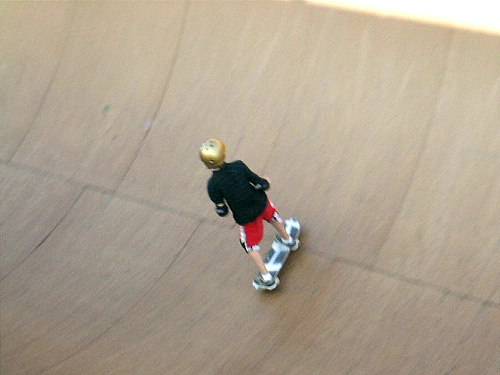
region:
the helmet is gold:
[198, 136, 225, 169]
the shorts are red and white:
[240, 196, 275, 244]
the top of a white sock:
[260, 270, 271, 282]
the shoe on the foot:
[250, 272, 277, 289]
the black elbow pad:
[213, 205, 228, 217]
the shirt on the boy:
[207, 160, 268, 225]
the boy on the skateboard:
[199, 137, 299, 289]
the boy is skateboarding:
[198, 136, 298, 288]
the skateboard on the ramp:
[253, 215, 299, 290]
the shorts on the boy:
[238, 197, 275, 247]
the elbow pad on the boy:
[214, 201, 229, 219]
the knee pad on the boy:
[237, 235, 260, 254]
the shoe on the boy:
[250, 272, 277, 290]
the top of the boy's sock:
[258, 271, 271, 282]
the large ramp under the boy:
[0, 0, 499, 372]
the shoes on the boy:
[253, 232, 300, 287]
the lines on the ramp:
[0, 0, 495, 373]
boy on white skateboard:
[196, 134, 307, 296]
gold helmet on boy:
[193, 133, 231, 168]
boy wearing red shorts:
[241, 195, 296, 250]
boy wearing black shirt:
[208, 157, 270, 225]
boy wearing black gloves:
[213, 175, 279, 215]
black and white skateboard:
[251, 214, 310, 296]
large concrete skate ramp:
[11, 0, 498, 353]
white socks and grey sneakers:
[254, 230, 299, 291]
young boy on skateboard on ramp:
[189, 132, 300, 304]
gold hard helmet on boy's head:
[199, 135, 226, 165]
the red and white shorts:
[238, 195, 278, 247]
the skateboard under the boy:
[254, 217, 300, 291]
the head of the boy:
[199, 135, 226, 170]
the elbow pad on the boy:
[213, 205, 228, 217]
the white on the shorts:
[237, 197, 274, 247]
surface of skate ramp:
[3, 2, 498, 373]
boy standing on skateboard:
[199, 138, 301, 289]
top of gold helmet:
[199, 138, 226, 169]